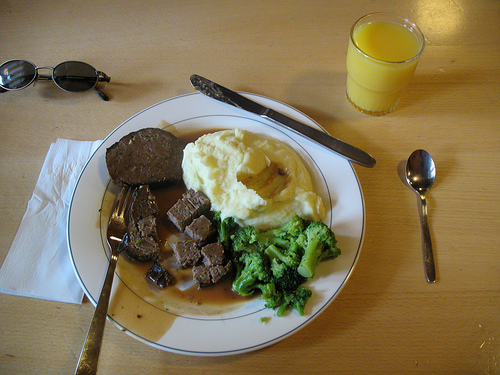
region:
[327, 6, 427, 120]
Full glass of orange juice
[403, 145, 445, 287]
Spoon on the table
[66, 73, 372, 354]
Meat, potatoes and veggies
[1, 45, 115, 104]
Sunglasses folded on the table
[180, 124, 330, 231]
Heaping pile of potatoes on the plate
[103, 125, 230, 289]
Meat partially cut up with gravy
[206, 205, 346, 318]
Broccoli between the potatoes and meat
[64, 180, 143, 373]
Fork on the plate in the gravy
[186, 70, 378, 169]
Knife on the edge of the plate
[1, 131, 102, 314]
Napkin on the left side of plate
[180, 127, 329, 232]
Mashed potatoes are on the plate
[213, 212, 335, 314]
Broccoli is on the plate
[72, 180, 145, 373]
Fork is on the plate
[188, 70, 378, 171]
Knife is on the plate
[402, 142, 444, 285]
Spoon is on the table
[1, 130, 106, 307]
Napkin is on the table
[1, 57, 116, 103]
Sunglasses are on the table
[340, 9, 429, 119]
Cup is on the table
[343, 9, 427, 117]
Cup is filled with orange juice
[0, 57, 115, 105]
Black sunglasses are on the table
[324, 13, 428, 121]
the glass has orange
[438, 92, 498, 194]
the table is wooden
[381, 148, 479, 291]
the spoon is silver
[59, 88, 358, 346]
the plate is white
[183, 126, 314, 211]
the mashpoatoe is on the plate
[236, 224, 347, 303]
broccolii is on the plate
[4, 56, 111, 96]
glasses are on the table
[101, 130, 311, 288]
the soup is on the plate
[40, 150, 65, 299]
the napkin is white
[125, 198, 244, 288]
liver is on the plate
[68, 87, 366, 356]
the round plate on the table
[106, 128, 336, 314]
the food on the plate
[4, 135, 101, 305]
the napkin next to the plate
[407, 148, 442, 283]
the spoon on the table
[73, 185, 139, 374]
the fork resting on the plate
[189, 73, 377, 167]
the knife resting on the plate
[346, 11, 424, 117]
the cup filled with orange juice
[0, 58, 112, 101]
the sunglasses on the table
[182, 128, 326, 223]
the pile of mashed potatoes on the plate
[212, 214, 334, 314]
the pile of broccoli on the plate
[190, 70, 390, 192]
The butter knife on the plate.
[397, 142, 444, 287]
The spoon on the table.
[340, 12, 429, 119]
The glass of orange juice on the table.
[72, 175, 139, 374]
The fork on the plate.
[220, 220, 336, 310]
The pieces of broccoli on the plate.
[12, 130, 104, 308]
The napkin on the table.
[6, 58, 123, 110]
The pair of sunglasses on the table.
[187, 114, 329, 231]
The mashed potatoes on the plate.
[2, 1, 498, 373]
The wooden table the items are placed on.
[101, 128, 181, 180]
The large piece of meatloaf on the plate.